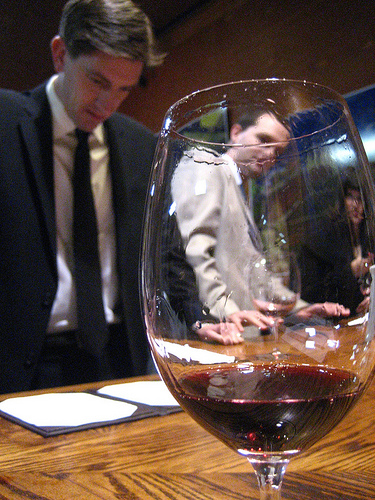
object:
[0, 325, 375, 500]
stained wood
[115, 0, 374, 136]
wall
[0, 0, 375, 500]
building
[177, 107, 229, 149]
image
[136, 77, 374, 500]
glass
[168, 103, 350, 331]
man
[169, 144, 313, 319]
jacket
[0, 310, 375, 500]
wood finish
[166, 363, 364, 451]
liquid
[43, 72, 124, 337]
shirt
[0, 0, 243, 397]
man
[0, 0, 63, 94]
wall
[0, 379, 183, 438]
menu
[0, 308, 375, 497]
table